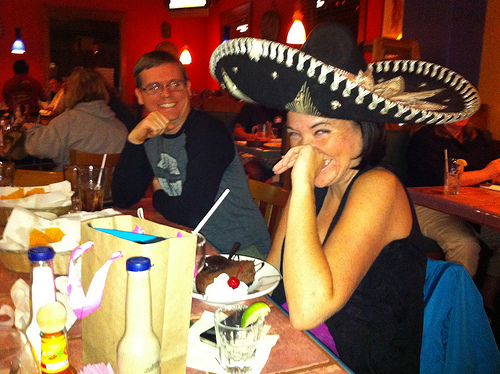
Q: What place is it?
A: It is a restaurant.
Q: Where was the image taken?
A: It was taken at the restaurant.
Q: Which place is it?
A: It is a restaurant.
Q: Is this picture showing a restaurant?
A: Yes, it is showing a restaurant.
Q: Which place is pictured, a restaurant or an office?
A: It is a restaurant.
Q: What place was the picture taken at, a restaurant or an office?
A: It was taken at a restaurant.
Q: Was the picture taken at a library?
A: No, the picture was taken in a restaurant.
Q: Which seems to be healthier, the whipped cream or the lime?
A: The lime is healthier than the whipped cream.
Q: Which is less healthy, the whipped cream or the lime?
A: The whipped cream is less healthy than the lime.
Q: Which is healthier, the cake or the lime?
A: The lime is healthier than the cake.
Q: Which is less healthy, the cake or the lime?
A: The cake is less healthy than the lime.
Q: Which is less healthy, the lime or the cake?
A: The cake is less healthy than the lime.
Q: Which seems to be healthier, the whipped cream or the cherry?
A: The cherry is healthier than the whipped cream.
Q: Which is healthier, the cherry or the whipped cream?
A: The cherry is healthier than the whipped cream.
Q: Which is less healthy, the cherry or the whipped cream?
A: The whipped cream is less healthy than the cherry.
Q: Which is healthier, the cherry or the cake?
A: The cherry is healthier than the cake.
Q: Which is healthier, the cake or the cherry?
A: The cherry is healthier than the cake.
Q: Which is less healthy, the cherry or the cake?
A: The cake is less healthy than the cherry.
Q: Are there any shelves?
A: No, there are no shelves.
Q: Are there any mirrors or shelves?
A: No, there are no shelves or mirrors.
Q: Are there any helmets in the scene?
A: No, there are no helmets.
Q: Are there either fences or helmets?
A: No, there are no helmets or fences.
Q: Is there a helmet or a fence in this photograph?
A: No, there are no helmets or fences.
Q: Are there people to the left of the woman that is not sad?
A: Yes, there is a person to the left of the woman.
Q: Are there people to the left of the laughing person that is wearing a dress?
A: Yes, there is a person to the left of the woman.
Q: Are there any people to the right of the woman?
A: No, the person is to the left of the woman.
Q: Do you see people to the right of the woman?
A: No, the person is to the left of the woman.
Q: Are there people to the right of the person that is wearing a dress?
A: No, the person is to the left of the woman.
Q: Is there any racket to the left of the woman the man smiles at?
A: No, there is a person to the left of the woman.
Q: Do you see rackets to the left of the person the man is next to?
A: No, there is a person to the left of the woman.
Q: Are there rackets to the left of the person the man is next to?
A: No, there is a person to the left of the woman.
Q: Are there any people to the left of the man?
A: Yes, there is a person to the left of the man.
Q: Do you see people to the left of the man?
A: Yes, there is a person to the left of the man.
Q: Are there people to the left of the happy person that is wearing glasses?
A: Yes, there is a person to the left of the man.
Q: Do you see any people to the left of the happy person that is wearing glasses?
A: Yes, there is a person to the left of the man.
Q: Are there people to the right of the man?
A: No, the person is to the left of the man.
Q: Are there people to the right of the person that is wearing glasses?
A: No, the person is to the left of the man.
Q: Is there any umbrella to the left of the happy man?
A: No, there is a person to the left of the man.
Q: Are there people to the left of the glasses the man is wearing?
A: Yes, there is a person to the left of the glasses.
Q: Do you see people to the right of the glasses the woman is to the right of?
A: No, the person is to the left of the glasses.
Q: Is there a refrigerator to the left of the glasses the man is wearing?
A: No, there is a person to the left of the glasses.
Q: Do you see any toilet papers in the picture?
A: No, there are no toilet papers.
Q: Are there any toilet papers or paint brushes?
A: No, there are no toilet papers or paint brushes.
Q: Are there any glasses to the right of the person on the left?
A: Yes, there are glasses to the right of the person.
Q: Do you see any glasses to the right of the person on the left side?
A: Yes, there are glasses to the right of the person.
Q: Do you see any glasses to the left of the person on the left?
A: No, the glasses are to the right of the person.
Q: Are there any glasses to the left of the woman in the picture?
A: Yes, there are glasses to the left of the woman.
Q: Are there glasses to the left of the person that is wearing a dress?
A: Yes, there are glasses to the left of the woman.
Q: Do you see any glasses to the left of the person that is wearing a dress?
A: Yes, there are glasses to the left of the woman.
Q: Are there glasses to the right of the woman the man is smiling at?
A: No, the glasses are to the left of the woman.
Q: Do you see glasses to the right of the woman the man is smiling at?
A: No, the glasses are to the left of the woman.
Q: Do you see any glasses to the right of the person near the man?
A: No, the glasses are to the left of the woman.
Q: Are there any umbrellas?
A: No, there are no umbrellas.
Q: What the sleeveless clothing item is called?
A: The clothing item is a dress.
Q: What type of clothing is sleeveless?
A: The clothing is a dress.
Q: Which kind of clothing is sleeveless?
A: The clothing is a dress.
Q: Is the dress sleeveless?
A: Yes, the dress is sleeveless.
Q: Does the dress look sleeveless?
A: Yes, the dress is sleeveless.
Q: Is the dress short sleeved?
A: No, the dress is sleeveless.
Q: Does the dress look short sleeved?
A: No, the dress is sleeveless.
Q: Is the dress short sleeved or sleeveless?
A: The dress is sleeveless.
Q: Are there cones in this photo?
A: No, there are no cones.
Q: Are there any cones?
A: No, there are no cones.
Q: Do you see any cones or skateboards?
A: No, there are no cones or skateboards.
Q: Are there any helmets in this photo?
A: No, there are no helmets.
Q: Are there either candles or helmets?
A: No, there are no helmets or candles.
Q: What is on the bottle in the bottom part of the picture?
A: The lid is on the bottle.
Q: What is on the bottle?
A: The lid is on the bottle.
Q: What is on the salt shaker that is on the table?
A: The lid is on the salt shaker.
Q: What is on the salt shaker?
A: The lid is on the salt shaker.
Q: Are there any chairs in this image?
A: Yes, there is a chair.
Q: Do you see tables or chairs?
A: Yes, there is a chair.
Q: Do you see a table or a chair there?
A: Yes, there is a chair.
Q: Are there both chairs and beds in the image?
A: No, there is a chair but no beds.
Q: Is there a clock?
A: No, there are no clocks.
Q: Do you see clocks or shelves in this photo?
A: No, there are no clocks or shelves.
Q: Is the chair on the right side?
A: Yes, the chair is on the right of the image.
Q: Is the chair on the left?
A: No, the chair is on the right of the image.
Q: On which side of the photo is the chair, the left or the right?
A: The chair is on the right of the image.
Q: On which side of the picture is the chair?
A: The chair is on the right of the image.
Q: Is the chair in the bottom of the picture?
A: Yes, the chair is in the bottom of the image.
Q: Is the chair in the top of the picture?
A: No, the chair is in the bottom of the image.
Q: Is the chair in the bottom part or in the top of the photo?
A: The chair is in the bottom of the image.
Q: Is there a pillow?
A: No, there are no pillows.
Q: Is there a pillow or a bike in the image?
A: No, there are no pillows or bikes.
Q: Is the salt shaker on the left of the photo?
A: Yes, the salt shaker is on the left of the image.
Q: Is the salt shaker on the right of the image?
A: No, the salt shaker is on the left of the image.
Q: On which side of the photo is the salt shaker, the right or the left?
A: The salt shaker is on the left of the image.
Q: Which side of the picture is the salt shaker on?
A: The salt shaker is on the left of the image.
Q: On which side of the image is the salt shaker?
A: The salt shaker is on the left of the image.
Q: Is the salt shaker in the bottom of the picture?
A: Yes, the salt shaker is in the bottom of the image.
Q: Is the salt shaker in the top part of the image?
A: No, the salt shaker is in the bottom of the image.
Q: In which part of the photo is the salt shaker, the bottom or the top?
A: The salt shaker is in the bottom of the image.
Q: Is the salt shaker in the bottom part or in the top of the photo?
A: The salt shaker is in the bottom of the image.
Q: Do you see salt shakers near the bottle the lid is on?
A: Yes, there is a salt shaker near the bottle.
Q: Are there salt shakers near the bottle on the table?
A: Yes, there is a salt shaker near the bottle.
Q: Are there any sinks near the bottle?
A: No, there is a salt shaker near the bottle.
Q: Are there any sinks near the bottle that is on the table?
A: No, there is a salt shaker near the bottle.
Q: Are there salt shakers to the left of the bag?
A: Yes, there is a salt shaker to the left of the bag.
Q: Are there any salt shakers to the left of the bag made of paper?
A: Yes, there is a salt shaker to the left of the bag.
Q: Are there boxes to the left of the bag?
A: No, there is a salt shaker to the left of the bag.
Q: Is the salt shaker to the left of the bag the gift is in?
A: Yes, the salt shaker is to the left of the bag.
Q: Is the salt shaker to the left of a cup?
A: No, the salt shaker is to the left of the bag.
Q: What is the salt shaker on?
A: The salt shaker is on the table.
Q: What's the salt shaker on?
A: The salt shaker is on the table.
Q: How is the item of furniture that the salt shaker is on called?
A: The piece of furniture is a table.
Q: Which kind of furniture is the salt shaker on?
A: The salt shaker is on the table.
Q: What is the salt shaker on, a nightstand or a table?
A: The salt shaker is on a table.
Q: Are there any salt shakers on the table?
A: Yes, there is a salt shaker on the table.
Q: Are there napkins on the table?
A: No, there is a salt shaker on the table.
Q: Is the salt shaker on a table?
A: Yes, the salt shaker is on a table.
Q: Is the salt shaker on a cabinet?
A: No, the salt shaker is on a table.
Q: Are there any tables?
A: Yes, there is a table.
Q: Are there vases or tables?
A: Yes, there is a table.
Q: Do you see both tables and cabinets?
A: No, there is a table but no cabinets.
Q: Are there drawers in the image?
A: No, there are no drawers.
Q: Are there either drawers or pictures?
A: No, there are no drawers or pictures.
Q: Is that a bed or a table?
A: That is a table.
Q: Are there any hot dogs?
A: No, there are no hot dogs.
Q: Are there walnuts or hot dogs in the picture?
A: No, there are no hot dogs or walnuts.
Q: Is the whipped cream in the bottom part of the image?
A: Yes, the whipped cream is in the bottom of the image.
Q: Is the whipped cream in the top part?
A: No, the whipped cream is in the bottom of the image.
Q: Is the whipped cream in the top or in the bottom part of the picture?
A: The whipped cream is in the bottom of the image.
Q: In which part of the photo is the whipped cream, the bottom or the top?
A: The whipped cream is in the bottom of the image.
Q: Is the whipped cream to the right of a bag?
A: Yes, the whipped cream is to the right of a bag.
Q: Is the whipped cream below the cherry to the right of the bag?
A: Yes, the whipped cream is below the cherry.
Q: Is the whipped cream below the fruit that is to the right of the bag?
A: Yes, the whipped cream is below the cherry.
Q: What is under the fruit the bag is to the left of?
A: The whipped cream is under the cherry.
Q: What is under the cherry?
A: The whipped cream is under the cherry.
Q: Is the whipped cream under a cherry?
A: Yes, the whipped cream is under a cherry.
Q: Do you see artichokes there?
A: No, there are no artichokes.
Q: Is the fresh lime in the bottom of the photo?
A: Yes, the lime is in the bottom of the image.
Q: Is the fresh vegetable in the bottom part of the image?
A: Yes, the lime is in the bottom of the image.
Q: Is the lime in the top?
A: No, the lime is in the bottom of the image.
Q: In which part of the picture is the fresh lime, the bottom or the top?
A: The lime is in the bottom of the image.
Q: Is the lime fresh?
A: Yes, the lime is fresh.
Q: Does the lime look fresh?
A: Yes, the lime is fresh.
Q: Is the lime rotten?
A: No, the lime is fresh.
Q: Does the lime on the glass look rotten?
A: No, the lime is fresh.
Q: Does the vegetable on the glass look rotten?
A: No, the lime is fresh.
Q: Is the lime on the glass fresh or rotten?
A: The lime is fresh.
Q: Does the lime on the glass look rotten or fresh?
A: The lime is fresh.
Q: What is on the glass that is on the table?
A: The lime is on the glass.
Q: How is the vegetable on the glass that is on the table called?
A: The vegetable is a lime.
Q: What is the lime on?
A: The lime is on the glass.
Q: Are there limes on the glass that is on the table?
A: Yes, there is a lime on the glass.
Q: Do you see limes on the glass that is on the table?
A: Yes, there is a lime on the glass.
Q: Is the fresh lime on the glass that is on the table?
A: Yes, the lime is on the glass.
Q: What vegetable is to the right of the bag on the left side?
A: The vegetable is a lime.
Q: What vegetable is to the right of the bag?
A: The vegetable is a lime.